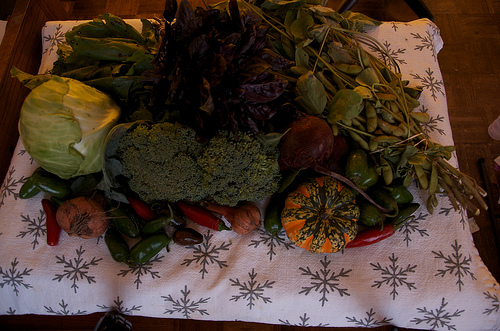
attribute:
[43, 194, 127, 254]
vegetable — small, round, pink, root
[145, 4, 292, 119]
lettuce — purple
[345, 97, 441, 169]
green beans — dark green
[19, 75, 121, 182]
lettuce — red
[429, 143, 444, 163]
ground — green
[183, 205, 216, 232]
red pepper — small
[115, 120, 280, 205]
broccoli — green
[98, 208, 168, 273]
peppers — small, green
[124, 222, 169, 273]
pepper — dark green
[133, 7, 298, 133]
leafy vegetable — dark purple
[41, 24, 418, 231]
vegetables — green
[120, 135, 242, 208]
heads — dark green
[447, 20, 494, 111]
flooring — brown, parkay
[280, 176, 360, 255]
gourd — round, orange, green, small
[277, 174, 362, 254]
squash — green, orange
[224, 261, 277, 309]
snowflake — gray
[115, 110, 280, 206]
broccoli — green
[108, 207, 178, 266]
peppers — green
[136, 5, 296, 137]
lettuce — red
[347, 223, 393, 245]
pepper — red, chili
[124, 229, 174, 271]
pepper — chili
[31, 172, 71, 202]
pepper — green, chili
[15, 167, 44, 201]
pepper — green, chili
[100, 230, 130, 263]
pepper — green, chili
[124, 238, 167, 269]
pepper — green, chili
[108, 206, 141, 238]
pepper — green, chili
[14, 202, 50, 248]
snowflake — gray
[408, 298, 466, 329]
snowflake — gray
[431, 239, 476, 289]
snowflake — gray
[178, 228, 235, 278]
snowflake — gray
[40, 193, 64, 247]
pepper — red, chili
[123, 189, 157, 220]
pepper — red, chili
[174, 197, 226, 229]
pepper — red, chili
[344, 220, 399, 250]
pepper — red, chili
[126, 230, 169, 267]
peppers — green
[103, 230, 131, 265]
peppers — green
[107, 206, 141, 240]
peppers — green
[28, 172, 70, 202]
peppers — green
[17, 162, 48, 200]
peppers — green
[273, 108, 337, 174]
radish — red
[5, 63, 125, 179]
cabbage — whole, head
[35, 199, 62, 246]
peppers — red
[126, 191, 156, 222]
peppers — red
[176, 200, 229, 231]
peppers — red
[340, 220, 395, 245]
peppers — red